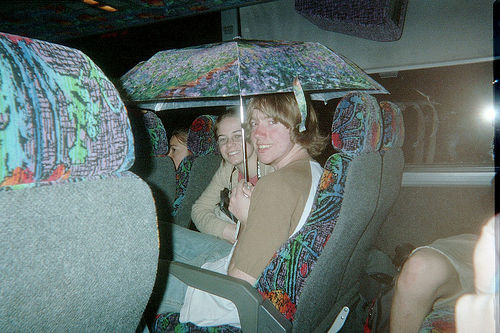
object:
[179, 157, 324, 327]
short sleeve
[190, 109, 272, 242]
girl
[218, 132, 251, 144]
glasses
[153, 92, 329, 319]
boy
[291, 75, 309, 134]
strap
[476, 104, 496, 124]
light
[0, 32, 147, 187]
headrest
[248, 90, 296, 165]
face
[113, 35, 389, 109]
umbrella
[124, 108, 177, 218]
seats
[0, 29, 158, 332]
back seat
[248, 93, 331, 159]
hair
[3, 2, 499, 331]
bus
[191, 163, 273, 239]
sweater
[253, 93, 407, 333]
gray/colorful seats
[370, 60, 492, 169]
window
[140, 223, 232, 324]
jeans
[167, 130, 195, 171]
head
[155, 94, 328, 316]
couple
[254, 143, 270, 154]
smile